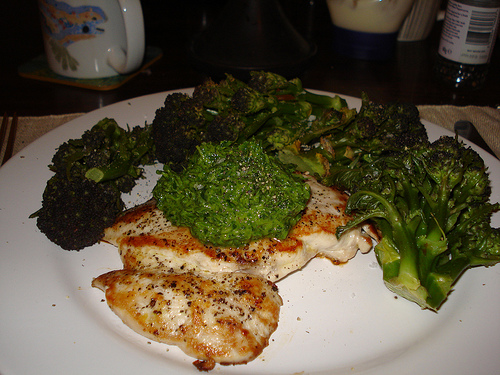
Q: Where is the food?
A: On the plate.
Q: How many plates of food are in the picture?
A: One.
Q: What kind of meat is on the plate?
A: Chicken.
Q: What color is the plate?
A: White.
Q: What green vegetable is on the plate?
A: Broccoli.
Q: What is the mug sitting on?
A: Coaster.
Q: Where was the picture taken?
A: At a table.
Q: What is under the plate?
A: Placemat.